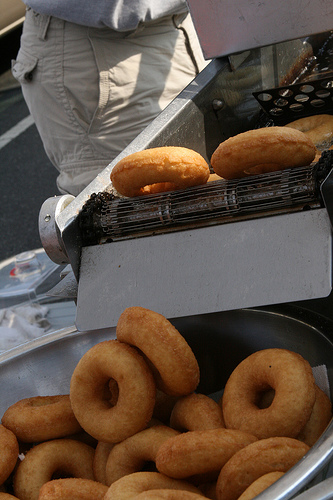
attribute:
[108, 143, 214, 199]
donut — golden, unglazed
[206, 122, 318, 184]
donut — golden, unglazed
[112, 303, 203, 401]
donut — golden, yummy looking, unglazed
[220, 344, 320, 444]
donut — golden, yummy looking, unglazed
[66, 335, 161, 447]
donut — golden, yummy looking, unglazed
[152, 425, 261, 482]
donut — yummy looking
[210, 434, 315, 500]
donut — yummy looking